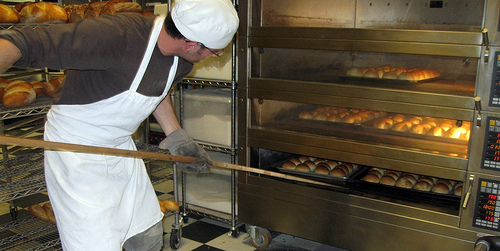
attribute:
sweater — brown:
[11, 27, 215, 99]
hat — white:
[169, 1, 239, 51]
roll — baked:
[329, 165, 348, 182]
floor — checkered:
[178, 219, 233, 249]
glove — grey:
[165, 134, 210, 174]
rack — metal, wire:
[0, 0, 183, 250]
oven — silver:
[227, 1, 499, 248]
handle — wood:
[191, 132, 348, 217]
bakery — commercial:
[0, 7, 495, 249]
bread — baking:
[278, 101, 469, 146]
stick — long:
[0, 123, 349, 203]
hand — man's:
[160, 131, 215, 176]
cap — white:
[174, 0, 242, 54]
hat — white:
[171, 0, 265, 67]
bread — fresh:
[387, 115, 457, 147]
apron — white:
[41, 14, 178, 248]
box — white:
[171, 87, 236, 148]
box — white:
[172, 146, 241, 218]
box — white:
[186, 42, 240, 84]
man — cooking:
[3, 7, 234, 247]